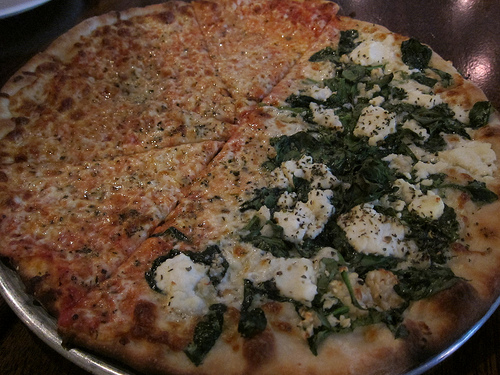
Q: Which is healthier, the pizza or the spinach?
A: The spinach is healthier than the pizza.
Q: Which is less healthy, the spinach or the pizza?
A: The pizza is less healthy than the spinach.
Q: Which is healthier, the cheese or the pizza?
A: The cheese is healthier than the pizza.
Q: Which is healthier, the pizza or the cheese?
A: The cheese is healthier than the pizza.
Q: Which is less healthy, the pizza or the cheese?
A: The pizza is less healthy than the cheese.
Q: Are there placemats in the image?
A: No, there are no placemats.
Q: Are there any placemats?
A: No, there are no placemats.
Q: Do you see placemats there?
A: No, there are no placemats.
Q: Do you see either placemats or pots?
A: No, there are no placemats or pots.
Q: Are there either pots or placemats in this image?
A: No, there are no placemats or pots.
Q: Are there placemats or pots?
A: No, there are no placemats or pots.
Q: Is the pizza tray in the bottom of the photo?
A: Yes, the pizza tray is in the bottom of the image.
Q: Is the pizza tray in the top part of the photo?
A: No, the pizza tray is in the bottom of the image.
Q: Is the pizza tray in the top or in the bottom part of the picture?
A: The pizza tray is in the bottom of the image.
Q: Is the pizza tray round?
A: Yes, the pizza tray is round.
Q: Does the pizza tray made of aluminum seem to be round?
A: Yes, the pizza tray is round.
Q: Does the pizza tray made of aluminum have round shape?
A: Yes, the pizza tray is round.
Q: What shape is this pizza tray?
A: The pizza tray is round.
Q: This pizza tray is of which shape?
A: The pizza tray is round.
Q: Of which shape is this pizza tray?
A: The pizza tray is round.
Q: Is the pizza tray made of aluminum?
A: Yes, the pizza tray is made of aluminum.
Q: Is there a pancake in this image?
A: No, there are no pancakes.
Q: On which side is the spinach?
A: The spinach is on the right of the image.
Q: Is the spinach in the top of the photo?
A: Yes, the spinach is in the top of the image.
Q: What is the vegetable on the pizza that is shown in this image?
A: The vegetable is spinach.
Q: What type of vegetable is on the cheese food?
A: The vegetable is spinach.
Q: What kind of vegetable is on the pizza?
A: The vegetable is spinach.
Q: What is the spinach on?
A: The spinach is on the pizza.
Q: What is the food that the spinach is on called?
A: The food is a pizza.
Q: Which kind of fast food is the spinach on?
A: The spinach is on the pizza.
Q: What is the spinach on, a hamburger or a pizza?
A: The spinach is on a pizza.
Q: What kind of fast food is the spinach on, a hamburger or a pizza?
A: The spinach is on a pizza.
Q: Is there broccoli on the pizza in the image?
A: No, there is spinach on the pizza.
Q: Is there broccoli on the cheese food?
A: No, there is spinach on the pizza.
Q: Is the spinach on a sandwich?
A: No, the spinach is on the pizza.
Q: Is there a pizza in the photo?
A: Yes, there is a pizza.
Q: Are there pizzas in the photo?
A: Yes, there is a pizza.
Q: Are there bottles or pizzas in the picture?
A: Yes, there is a pizza.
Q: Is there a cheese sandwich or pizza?
A: Yes, there is a cheese pizza.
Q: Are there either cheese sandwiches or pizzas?
A: Yes, there is a cheese pizza.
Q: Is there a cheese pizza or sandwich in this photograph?
A: Yes, there is a cheese pizza.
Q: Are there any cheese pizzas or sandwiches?
A: Yes, there is a cheese pizza.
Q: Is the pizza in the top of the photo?
A: Yes, the pizza is in the top of the image.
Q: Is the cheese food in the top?
A: Yes, the pizza is in the top of the image.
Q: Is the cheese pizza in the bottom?
A: No, the pizza is in the top of the image.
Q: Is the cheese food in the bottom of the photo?
A: No, the pizza is in the top of the image.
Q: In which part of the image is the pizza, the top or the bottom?
A: The pizza is in the top of the image.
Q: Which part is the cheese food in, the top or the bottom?
A: The pizza is in the top of the image.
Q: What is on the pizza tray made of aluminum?
A: The pizza is on the pizza tray.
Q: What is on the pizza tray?
A: The pizza is on the pizza tray.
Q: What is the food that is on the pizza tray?
A: The food is a pizza.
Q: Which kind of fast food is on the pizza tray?
A: The food is a pizza.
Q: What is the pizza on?
A: The pizza is on the pizza tray.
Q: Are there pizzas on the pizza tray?
A: Yes, there is a pizza on the pizza tray.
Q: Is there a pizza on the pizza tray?
A: Yes, there is a pizza on the pizza tray.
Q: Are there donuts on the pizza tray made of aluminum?
A: No, there is a pizza on the pizza tray.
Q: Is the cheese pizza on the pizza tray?
A: Yes, the pizza is on the pizza tray.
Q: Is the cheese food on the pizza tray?
A: Yes, the pizza is on the pizza tray.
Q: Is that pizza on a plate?
A: No, the pizza is on the pizza tray.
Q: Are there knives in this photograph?
A: No, there are no knives.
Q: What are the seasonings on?
A: The seasonings are on the pizza.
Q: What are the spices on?
A: The seasonings are on the pizza.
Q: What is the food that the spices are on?
A: The food is a pizza.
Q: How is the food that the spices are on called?
A: The food is a pizza.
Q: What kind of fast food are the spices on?
A: The spices are on the pizza.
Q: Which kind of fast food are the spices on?
A: The spices are on the pizza.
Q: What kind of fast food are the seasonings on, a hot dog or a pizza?
A: The seasonings are on a pizza.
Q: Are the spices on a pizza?
A: Yes, the spices are on a pizza.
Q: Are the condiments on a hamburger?
A: No, the condiments are on a pizza.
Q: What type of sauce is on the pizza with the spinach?
A: The sauce is tomato sauce.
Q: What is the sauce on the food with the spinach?
A: The sauce is tomato sauce.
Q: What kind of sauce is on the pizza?
A: The sauce is tomato sauce.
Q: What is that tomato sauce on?
A: The tomato sauce is on the pizza.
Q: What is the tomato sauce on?
A: The tomato sauce is on the pizza.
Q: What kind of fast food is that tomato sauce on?
A: The tomato sauce is on the pizza.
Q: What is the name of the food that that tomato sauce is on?
A: The food is a pizza.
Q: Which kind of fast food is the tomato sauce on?
A: The tomato sauce is on the pizza.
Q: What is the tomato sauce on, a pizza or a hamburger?
A: The tomato sauce is on a pizza.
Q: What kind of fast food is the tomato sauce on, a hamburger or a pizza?
A: The tomato sauce is on a pizza.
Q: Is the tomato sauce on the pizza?
A: Yes, the tomato sauce is on the pizza.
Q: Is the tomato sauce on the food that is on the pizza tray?
A: Yes, the tomato sauce is on the pizza.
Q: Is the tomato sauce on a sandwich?
A: No, the tomato sauce is on the pizza.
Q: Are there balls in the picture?
A: No, there are no balls.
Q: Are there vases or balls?
A: No, there are no balls or vases.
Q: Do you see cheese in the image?
A: Yes, there is cheese.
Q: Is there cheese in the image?
A: Yes, there is cheese.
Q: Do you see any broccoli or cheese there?
A: Yes, there is cheese.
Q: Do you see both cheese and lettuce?
A: No, there is cheese but no lettuce.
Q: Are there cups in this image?
A: No, there are no cups.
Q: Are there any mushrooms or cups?
A: No, there are no cups or mushrooms.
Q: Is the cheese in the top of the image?
A: Yes, the cheese is in the top of the image.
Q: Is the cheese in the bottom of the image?
A: No, the cheese is in the top of the image.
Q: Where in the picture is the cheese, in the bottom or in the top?
A: The cheese is in the top of the image.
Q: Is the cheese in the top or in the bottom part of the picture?
A: The cheese is in the top of the image.